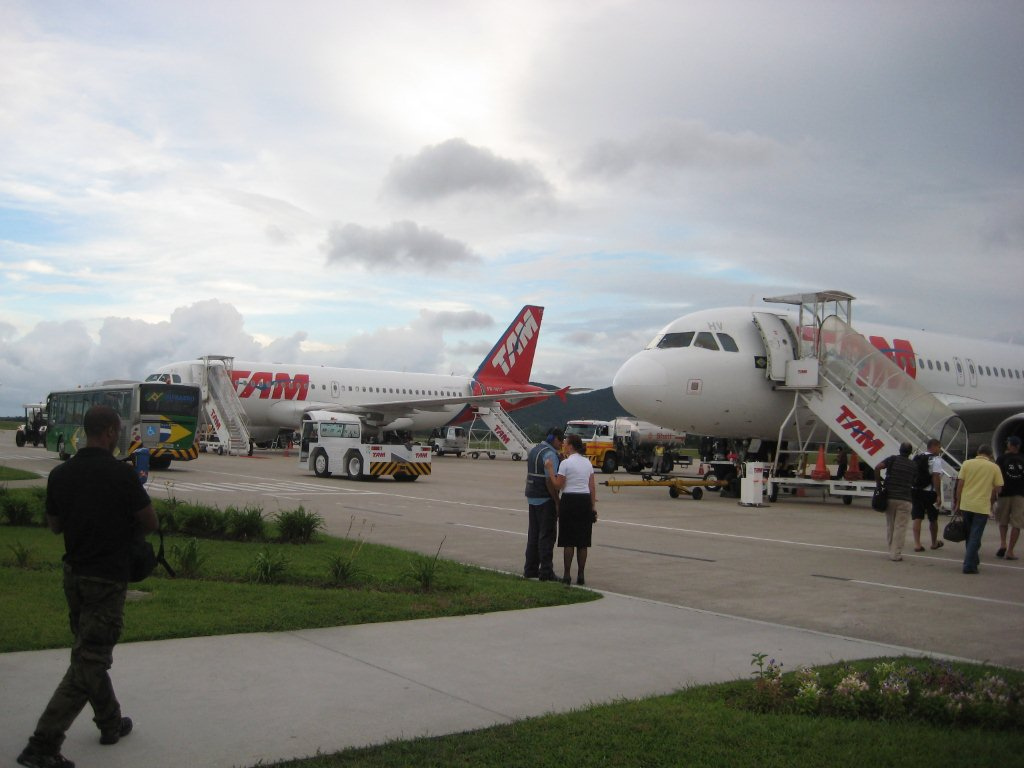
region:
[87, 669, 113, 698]
leg of the person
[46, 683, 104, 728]
leg of the person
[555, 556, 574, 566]
leg of the person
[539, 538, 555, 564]
leg of the person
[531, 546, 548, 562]
leg of the person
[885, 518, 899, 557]
leg of the person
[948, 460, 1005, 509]
a man wearing a yellow shirt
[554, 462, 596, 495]
a woman wearing a white shirt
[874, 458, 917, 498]
a man wearing a brown shirt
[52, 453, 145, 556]
a man wearing a black shirt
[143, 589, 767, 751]
a concrete sidewalk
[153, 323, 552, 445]
a red and white airplane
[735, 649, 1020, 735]
a small patch of flowers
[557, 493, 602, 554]
a woman wearing a black skirt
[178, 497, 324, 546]
a row of small green bushes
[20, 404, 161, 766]
Person is walking to the plane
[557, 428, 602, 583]
Person is walking to the plane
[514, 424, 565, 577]
Person is walking to the plane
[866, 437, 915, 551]
Person is walking to the plane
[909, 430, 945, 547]
Person is walking to the plane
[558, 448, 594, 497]
Woman is wearing a white shirt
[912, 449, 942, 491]
Man is wearing a white shirt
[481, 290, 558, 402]
tail of a plane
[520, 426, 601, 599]
two people standing near airport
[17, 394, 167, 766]
man walking on sidewalk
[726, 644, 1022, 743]
flowers in the grass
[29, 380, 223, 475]
bus on the road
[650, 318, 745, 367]
front windows of a plane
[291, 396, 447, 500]
airport vehicle on the road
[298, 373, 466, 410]
side windows of a plane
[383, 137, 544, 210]
cloud in the sky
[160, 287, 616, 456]
large white plane on ground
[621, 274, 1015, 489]
large white plane on ground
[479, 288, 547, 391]
red tail of plane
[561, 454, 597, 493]
white short sleeve shirt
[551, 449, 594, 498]
a woman's white short sleeve shirt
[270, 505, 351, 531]
a small green bush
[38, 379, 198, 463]
a large green and white bus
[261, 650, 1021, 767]
a section of green grass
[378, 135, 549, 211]
a large white cloud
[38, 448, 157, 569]
a man's short sleeve black shirt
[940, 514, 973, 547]
a small black bag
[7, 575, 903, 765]
a paved sidewalk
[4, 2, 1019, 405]
cloud cover in daytime sky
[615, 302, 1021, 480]
nose of white plane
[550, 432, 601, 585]
woman in white shirt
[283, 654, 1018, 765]
surface of green grass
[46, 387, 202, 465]
back of parked bus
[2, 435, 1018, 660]
surface of airport tarmac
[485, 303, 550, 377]
white letters on red plane tail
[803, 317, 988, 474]
cover over boarding ramp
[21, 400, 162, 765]
walking man carrying bag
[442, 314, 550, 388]
The tail of the plane is red.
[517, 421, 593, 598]
People standing near the sidewalk.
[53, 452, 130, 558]
The shirt is black.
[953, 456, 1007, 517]
The shirt is yellow.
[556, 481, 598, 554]
The person is wearing a black skirt.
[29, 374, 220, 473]
A bus on the road.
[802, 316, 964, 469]
Staircase to the airplane.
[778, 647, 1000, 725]
White flowers on the grass.